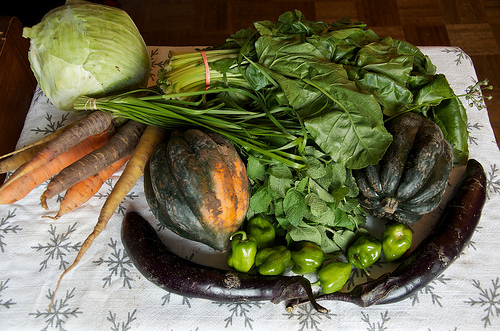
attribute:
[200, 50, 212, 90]
rubber band — red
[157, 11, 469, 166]
bunch — spinach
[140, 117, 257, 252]
corn — squash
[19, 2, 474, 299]
vegetables — green, leafy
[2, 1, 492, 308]
produce — home grown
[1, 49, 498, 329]
linen sheet — white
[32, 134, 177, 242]
carrots — long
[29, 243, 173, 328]
cloth — white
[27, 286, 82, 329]
snow flake — silver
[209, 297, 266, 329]
snow flake — silver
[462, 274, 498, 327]
snow flake — silver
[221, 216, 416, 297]
peppers — green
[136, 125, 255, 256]
squash — over-ripe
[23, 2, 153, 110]
cabbage — light green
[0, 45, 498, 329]
table cloth — white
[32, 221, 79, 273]
snowflake — gray, printed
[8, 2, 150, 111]
cabbage — round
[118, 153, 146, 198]
carrot — long, orange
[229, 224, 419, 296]
peppers — green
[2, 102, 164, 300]
carrots — orange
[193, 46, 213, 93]
rubberband — red